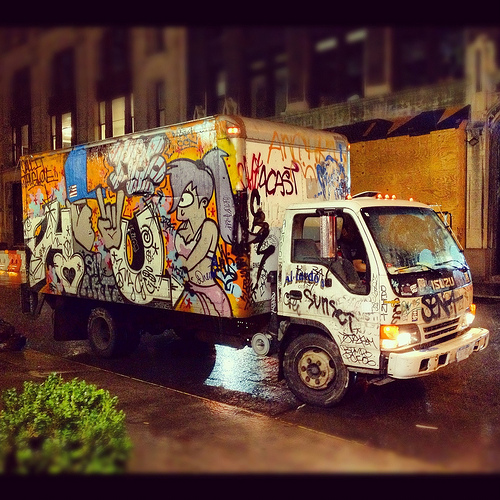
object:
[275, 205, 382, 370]
door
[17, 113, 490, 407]
truck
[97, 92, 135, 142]
windows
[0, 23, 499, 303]
building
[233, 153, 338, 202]
writing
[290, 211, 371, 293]
window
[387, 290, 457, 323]
graffiti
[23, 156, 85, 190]
graffiti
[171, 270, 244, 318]
graffiti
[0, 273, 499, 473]
pavement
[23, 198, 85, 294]
character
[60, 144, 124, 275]
character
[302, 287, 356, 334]
sunset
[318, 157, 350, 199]
graffiti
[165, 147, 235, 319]
girl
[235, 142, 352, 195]
graffiti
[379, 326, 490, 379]
bumper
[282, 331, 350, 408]
tire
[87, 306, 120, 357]
tire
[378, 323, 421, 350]
headlight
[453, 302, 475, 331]
headlight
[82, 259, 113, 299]
graffiti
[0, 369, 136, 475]
bush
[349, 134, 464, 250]
wall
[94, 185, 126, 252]
hand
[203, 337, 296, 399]
reflection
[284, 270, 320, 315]
graffiti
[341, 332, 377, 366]
graffiti